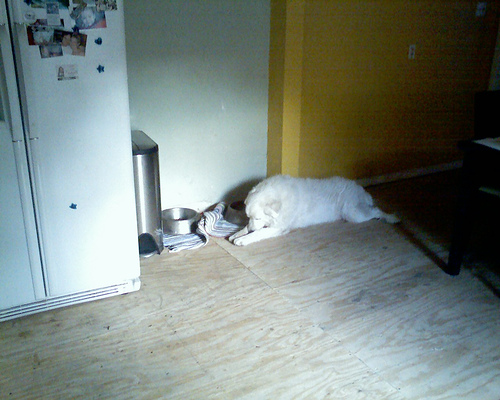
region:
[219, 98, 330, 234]
the dog is white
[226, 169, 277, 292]
the dog is white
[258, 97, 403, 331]
the dog is white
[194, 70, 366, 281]
the dog is white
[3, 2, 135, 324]
a white refrigerator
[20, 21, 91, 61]
pictures on a refrigerator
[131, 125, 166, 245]
a silvery and black trashcan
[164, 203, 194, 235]
a silvery bowl on a rug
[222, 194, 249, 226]
a bowl with dog food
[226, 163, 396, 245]
a white dog laying on the floor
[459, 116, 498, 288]
edge of a table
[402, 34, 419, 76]
a white electrical outlet on a yellow wall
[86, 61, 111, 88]
a fridge magnet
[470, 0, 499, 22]
white light switch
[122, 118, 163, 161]
THE TRASH CAN HAS A BLACK LID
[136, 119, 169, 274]
THE TRASH CAN IS SILVER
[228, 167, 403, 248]
THE DOG IS WHITE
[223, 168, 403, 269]
THE DOG IS LYING DOWN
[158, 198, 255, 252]
THE BOWL IS ON A RUG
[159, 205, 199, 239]
THE BOWL IS SILVER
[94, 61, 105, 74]
THE MAGNET IS ON THE FRIDGE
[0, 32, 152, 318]
THE FRIDGE IS WHITE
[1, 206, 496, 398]
THE FLOOR IS PLYWOOD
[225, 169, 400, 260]
THE DOG IS SLEEPING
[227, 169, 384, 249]
a white dog on floor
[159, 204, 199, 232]
a metal pet dish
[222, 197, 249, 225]
a metal pet dish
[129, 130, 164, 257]
a metal trash can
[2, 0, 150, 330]
a two door white refrigerator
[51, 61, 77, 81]
a rectangular refrigerator magnet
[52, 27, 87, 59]
a photograph of people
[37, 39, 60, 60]
a photograph of people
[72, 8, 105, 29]
a photograph of people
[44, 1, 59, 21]
a photograph of people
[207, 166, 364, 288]
the dog is white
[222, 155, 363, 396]
the dog is white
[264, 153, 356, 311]
the dog is white